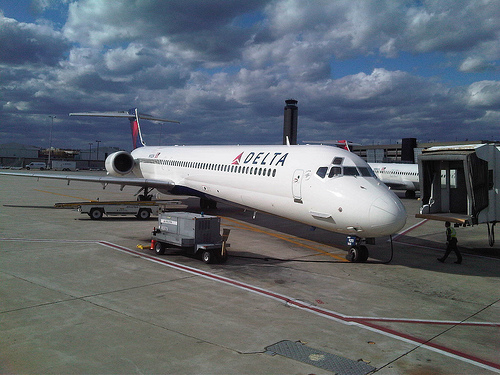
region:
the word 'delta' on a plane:
[243, 151, 288, 166]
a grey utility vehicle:
[140, 207, 226, 263]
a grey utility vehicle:
[55, 195, 177, 216]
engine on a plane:
[104, 149, 138, 177]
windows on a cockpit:
[316, 165, 376, 177]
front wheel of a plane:
[345, 236, 368, 265]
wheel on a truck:
[88, 205, 102, 221]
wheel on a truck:
[135, 208, 150, 220]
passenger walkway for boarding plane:
[416, 136, 498, 224]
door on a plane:
[291, 169, 303, 203]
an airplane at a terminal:
[11, 94, 416, 282]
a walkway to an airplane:
[413, 139, 498, 229]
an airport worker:
[437, 219, 462, 264]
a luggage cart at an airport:
[47, 194, 186, 218]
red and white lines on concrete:
[164, 258, 304, 305]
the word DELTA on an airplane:
[242, 151, 290, 166]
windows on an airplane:
[153, 157, 280, 176]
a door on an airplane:
[288, 165, 304, 204]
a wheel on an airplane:
[347, 240, 370, 267]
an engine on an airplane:
[106, 151, 134, 175]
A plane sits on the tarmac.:
[8, 105, 410, 250]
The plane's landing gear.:
[343, 237, 371, 264]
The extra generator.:
[150, 208, 228, 264]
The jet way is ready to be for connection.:
[414, 138, 495, 254]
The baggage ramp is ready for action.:
[55, 196, 167, 219]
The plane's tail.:
[66, 105, 182, 142]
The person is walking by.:
[438, 221, 466, 265]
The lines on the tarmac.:
[226, 261, 347, 334]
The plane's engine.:
[103, 148, 137, 180]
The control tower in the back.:
[278, 98, 301, 144]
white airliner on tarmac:
[105, 115, 457, 250]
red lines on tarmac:
[281, 293, 395, 344]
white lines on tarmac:
[264, 290, 341, 322]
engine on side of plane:
[104, 139, 136, 176]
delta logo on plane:
[234, 142, 302, 176]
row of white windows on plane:
[180, 160, 234, 174]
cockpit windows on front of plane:
[316, 158, 389, 190]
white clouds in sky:
[166, 21, 314, 83]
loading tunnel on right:
[417, 150, 499, 226]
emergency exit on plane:
[291, 167, 307, 207]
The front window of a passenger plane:
[316, 163, 378, 178]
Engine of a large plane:
[105, 149, 136, 176]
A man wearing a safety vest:
[438, 219, 463, 265]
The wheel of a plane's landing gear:
[349, 245, 368, 260]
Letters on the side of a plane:
[243, 149, 289, 168]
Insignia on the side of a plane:
[231, 148, 243, 164]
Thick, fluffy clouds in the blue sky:
[1, 0, 498, 152]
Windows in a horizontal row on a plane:
[138, 156, 278, 178]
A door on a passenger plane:
[291, 168, 303, 200]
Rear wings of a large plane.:
[66, 105, 181, 147]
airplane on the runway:
[16, 74, 413, 268]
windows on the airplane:
[313, 163, 373, 179]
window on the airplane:
[266, 165, 274, 176]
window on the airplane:
[248, 165, 255, 178]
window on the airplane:
[206, 163, 213, 170]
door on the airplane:
[288, 165, 306, 197]